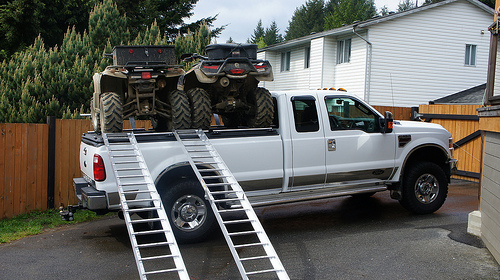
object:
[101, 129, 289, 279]
ramp ramp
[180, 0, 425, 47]
sky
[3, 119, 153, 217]
wooden fence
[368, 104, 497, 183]
wooden fence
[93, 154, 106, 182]
light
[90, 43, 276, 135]
four wheelers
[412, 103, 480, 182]
fence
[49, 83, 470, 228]
trailer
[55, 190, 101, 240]
hitch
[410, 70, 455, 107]
ground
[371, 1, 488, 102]
wall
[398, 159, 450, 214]
tire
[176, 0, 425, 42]
cloudy sky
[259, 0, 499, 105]
white house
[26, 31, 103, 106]
tree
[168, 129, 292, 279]
ramp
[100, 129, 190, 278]
ramp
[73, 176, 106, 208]
bumper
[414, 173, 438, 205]
wheel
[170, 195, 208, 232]
wheel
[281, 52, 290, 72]
window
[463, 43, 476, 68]
window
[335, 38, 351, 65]
window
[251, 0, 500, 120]
building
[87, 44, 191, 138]
four wheeler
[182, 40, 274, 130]
four wheeler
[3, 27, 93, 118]
trees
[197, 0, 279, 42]
sky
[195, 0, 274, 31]
clouds